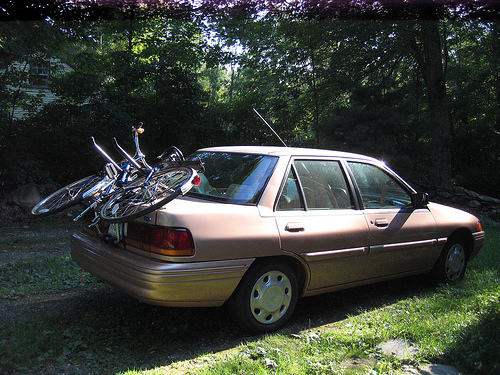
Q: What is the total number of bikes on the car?
A: 1.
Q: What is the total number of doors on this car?
A: Four.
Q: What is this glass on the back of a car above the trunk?
A: Windshield.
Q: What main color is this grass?
A: Green.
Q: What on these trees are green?
A: Leaves.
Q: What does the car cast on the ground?
A: Shadow.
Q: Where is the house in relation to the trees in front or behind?
A: Behind.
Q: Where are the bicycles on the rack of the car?
A: Trunk.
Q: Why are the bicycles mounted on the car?
A: Transportation.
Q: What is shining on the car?
A: Sun.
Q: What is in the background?
A: Trees.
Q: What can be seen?
A: Car.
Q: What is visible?
A: Car.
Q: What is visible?
A: Car.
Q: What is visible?
A: Car.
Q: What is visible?
A: Car.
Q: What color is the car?
A: Brown.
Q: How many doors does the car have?
A: Four.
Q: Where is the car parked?
A: Grass.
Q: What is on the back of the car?
A: Bikes.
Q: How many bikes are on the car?
A: Two.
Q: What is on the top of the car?
A: Antenna.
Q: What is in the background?
A: Trees.